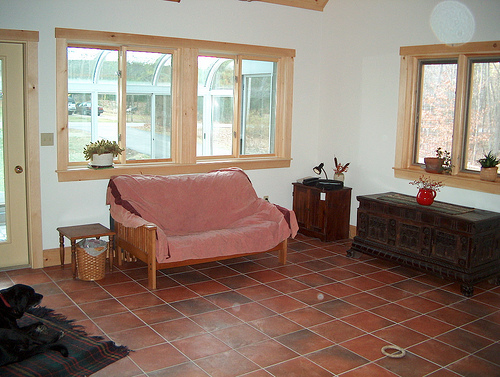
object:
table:
[55, 222, 118, 281]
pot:
[416, 188, 436, 205]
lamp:
[312, 162, 328, 182]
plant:
[83, 139, 124, 168]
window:
[124, 50, 173, 160]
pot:
[88, 152, 115, 168]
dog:
[0, 283, 68, 365]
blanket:
[1, 308, 133, 377]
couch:
[105, 166, 302, 290]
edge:
[120, 159, 177, 170]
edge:
[160, 224, 280, 248]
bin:
[75, 239, 109, 281]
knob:
[16, 165, 23, 173]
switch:
[40, 133, 54, 145]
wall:
[0, 0, 318, 267]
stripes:
[22, 312, 120, 361]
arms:
[112, 202, 159, 255]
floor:
[0, 233, 500, 377]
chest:
[291, 183, 353, 241]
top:
[57, 223, 117, 239]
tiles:
[170, 331, 233, 361]